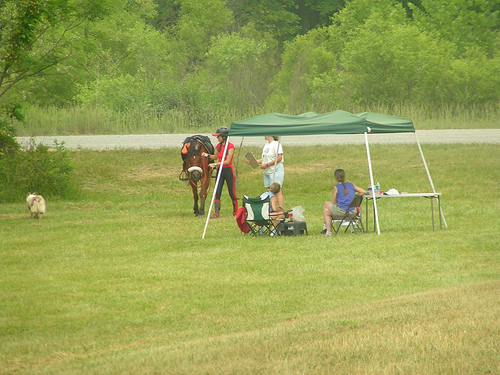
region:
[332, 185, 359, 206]
The lady is wearing a sleeveless blue shirt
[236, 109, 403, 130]
green roof being held up by white poles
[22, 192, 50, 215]
a white animal off by itself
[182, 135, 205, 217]
brown horse with head hung down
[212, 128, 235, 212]
lady wearing black and red clothes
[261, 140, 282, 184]
lady wearing white shorts and top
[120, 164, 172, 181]
a dry area of grass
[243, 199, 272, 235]
green and white lawn chair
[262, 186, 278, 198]
lady with short hair wearing light blue sleeveless shirt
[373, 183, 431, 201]
a water bottle sitting on table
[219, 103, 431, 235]
chairs under a green canopy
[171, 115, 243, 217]
a woman with a horse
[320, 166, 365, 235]
a person sitting on a folding chair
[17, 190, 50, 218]
a shaggy white dog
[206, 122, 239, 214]
a woman in a red and blue outfit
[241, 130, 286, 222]
a woman with a clip board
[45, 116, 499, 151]
a road with grass on both sides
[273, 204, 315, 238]
a grey stool with a drink on it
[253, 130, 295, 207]
a woman in a white shirt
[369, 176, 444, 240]
a folding table with drinks on it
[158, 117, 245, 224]
Woman tending to a horse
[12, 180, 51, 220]
White dog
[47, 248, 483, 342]
Green field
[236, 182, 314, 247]
Woman sitting in a green chair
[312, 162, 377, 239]
Woman sitting in a brown folding chair.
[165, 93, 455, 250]
A tent in a field.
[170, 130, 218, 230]
Brown Horse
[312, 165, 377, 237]
Woman in a blue shirt.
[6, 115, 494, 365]
Road behind the field.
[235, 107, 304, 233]
Woman with a clipboard.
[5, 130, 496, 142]
grey road in distance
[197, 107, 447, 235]
green canopy with white poles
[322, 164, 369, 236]
woman sitting in chair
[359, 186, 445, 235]
folding table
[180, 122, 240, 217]
person standing beside small horse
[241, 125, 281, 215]
woman standing and holding a clipboard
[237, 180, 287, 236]
woman sitting in low camp chair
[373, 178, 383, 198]
bottle of water on folding table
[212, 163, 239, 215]
woman wearing red and black pants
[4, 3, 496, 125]
many trees near road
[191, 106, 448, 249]
Green tent in the grass.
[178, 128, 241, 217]
Person next to a horse.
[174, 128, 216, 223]
Brown horse standing on grass.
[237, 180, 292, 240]
Person sitting in a chair.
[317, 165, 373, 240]
Person wearing a blue shirt.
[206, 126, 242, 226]
Person wearing a red shirt.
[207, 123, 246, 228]
Person wearing a black helmet.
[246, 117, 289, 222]
Person wearing a white shirt.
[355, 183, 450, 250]
White table in the grass.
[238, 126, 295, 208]
Person holding a clipboard.